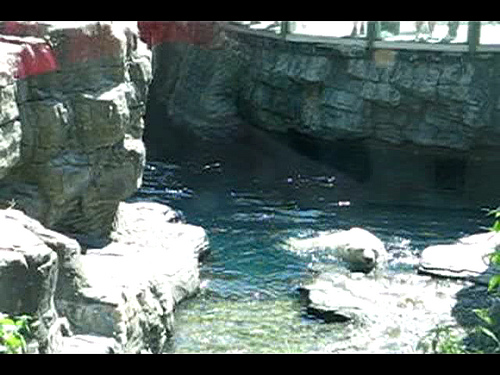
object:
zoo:
[0, 20, 500, 353]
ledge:
[82, 203, 204, 298]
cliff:
[44, 19, 155, 246]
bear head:
[345, 244, 384, 267]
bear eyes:
[361, 248, 376, 252]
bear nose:
[365, 257, 373, 261]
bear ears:
[345, 247, 385, 256]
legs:
[447, 20, 460, 36]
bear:
[289, 226, 389, 268]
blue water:
[219, 210, 280, 283]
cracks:
[16, 91, 55, 109]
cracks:
[30, 143, 117, 162]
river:
[127, 129, 498, 354]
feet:
[437, 34, 455, 44]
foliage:
[0, 308, 30, 356]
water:
[143, 126, 451, 343]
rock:
[0, 21, 209, 355]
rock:
[151, 24, 495, 148]